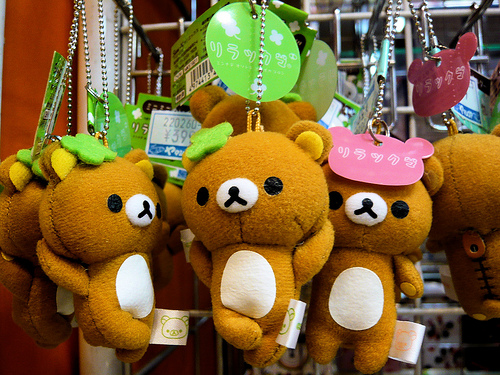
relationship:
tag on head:
[321, 121, 434, 191] [325, 118, 434, 190]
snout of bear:
[209, 174, 261, 219] [167, 119, 334, 359]